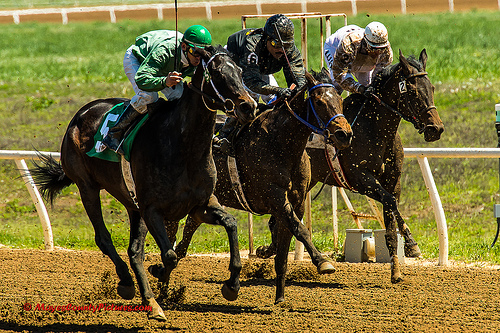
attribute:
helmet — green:
[180, 23, 212, 52]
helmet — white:
[363, 17, 392, 51]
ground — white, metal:
[322, 274, 442, 309]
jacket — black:
[225, 30, 307, 92]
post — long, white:
[296, 11, 311, 72]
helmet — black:
[261, 10, 296, 45]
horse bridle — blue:
[306, 99, 328, 123]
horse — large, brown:
[253, 48, 443, 285]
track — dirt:
[1, 245, 498, 331]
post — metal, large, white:
[420, 144, 461, 269]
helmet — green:
[177, 24, 212, 44]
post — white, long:
[96, 12, 141, 28]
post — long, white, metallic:
[198, 3, 216, 15]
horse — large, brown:
[201, 69, 353, 308]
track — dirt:
[1, 2, 498, 329]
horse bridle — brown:
[295, 89, 337, 132]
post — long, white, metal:
[414, 156, 458, 266]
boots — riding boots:
[95, 94, 138, 172]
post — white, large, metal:
[8, 149, 58, 249]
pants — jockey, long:
[124, 49, 186, 114]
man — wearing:
[97, 22, 212, 154]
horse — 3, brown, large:
[34, 40, 261, 313]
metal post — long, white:
[328, 179, 339, 259]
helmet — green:
[183, 23, 212, 48]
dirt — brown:
[0, 254, 499, 331]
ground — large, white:
[320, 230, 456, 332]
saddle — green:
[89, 105, 146, 162]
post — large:
[1, 2, 58, 26]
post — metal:
[131, 4, 193, 27]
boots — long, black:
[85, 124, 115, 167]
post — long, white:
[322, 146, 353, 257]